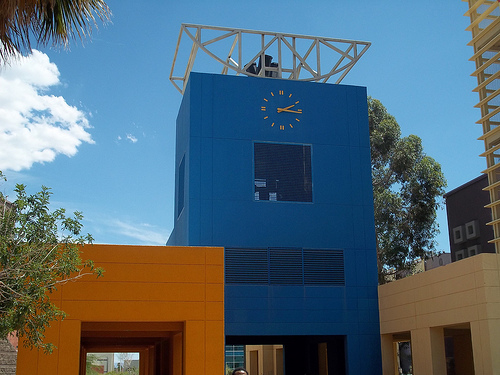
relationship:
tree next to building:
[370, 99, 449, 291] [169, 70, 380, 373]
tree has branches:
[0, 172, 106, 353] [11, 207, 101, 336]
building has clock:
[169, 70, 380, 373] [261, 87, 305, 130]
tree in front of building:
[0, 167, 111, 348] [11, 238, 228, 371]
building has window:
[165, 72, 383, 375] [210, 242, 349, 287]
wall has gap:
[226, 201, 376, 342] [231, 339, 338, 373]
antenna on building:
[164, 15, 376, 87] [140, 18, 396, 373]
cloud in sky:
[0, 34, 129, 234] [75, 79, 152, 177]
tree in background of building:
[370, 99, 449, 291] [169, 70, 380, 373]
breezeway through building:
[54, 305, 201, 373] [11, 224, 237, 371]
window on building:
[252, 137, 317, 201] [95, 22, 497, 374]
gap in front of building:
[225, 336, 346, 375] [169, 70, 380, 373]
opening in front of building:
[82, 314, 190, 372] [7, 233, 234, 360]